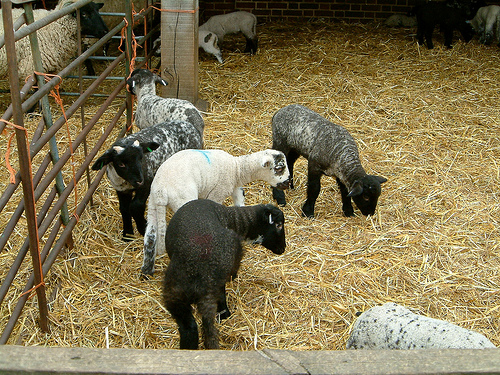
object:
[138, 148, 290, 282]
goat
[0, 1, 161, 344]
fence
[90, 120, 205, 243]
sheep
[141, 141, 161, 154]
ear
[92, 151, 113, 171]
ear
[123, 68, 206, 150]
sheep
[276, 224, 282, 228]
eye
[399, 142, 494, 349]
hay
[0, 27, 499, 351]
ground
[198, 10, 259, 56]
baby goats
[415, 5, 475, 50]
baby goat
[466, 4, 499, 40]
baby goat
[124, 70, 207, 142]
baby goat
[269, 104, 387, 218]
baby goat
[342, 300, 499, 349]
baby goat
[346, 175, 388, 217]
head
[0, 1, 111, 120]
sheep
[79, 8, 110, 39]
face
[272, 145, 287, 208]
legs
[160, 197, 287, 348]
goats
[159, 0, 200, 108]
post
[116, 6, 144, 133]
string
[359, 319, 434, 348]
spots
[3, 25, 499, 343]
pen